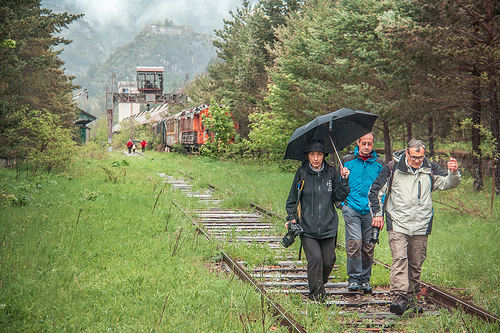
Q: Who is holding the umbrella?
A: The woman.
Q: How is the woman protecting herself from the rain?
A: With the umbrella.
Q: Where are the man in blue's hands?
A: In his pockets.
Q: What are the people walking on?
A: Train tracks.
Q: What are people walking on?
A: Train tracks.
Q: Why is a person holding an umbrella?
A: It is raining.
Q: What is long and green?
A: Grass.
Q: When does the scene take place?
A: During the daytime.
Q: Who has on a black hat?
A: Woman holding umbrella.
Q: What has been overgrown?
A: The grass.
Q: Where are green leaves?
A: The trees.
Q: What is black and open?
A: Umbrella.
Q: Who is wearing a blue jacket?
A: Man in the middle.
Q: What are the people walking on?
A: Train track.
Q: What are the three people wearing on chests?
A: Jackets.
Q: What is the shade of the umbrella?
A: Black.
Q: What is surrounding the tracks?
A: Trees.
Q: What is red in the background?
A: Train.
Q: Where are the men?
A: On train tracks.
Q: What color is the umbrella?
A: Black.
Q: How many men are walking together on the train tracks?
A: 3.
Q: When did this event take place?
A: Daytime.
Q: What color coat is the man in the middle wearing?
A: Blue.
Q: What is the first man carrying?
A: An umbrella.